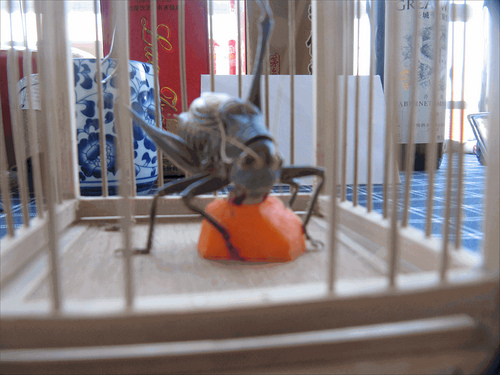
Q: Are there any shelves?
A: No, there are no shelves.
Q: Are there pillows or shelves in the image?
A: No, there are no shelves or pillows.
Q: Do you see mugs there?
A: Yes, there is a mug.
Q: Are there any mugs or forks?
A: Yes, there is a mug.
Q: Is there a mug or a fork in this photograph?
A: Yes, there is a mug.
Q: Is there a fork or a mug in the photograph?
A: Yes, there is a mug.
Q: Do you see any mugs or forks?
A: Yes, there is a mug.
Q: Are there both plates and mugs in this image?
A: No, there is a mug but no plates.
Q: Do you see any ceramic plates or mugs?
A: Yes, there is a porcelain mug.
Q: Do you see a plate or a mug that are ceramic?
A: Yes, the mug is ceramic.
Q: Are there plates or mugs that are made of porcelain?
A: Yes, the mug is made of porcelain.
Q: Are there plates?
A: No, there are no plates.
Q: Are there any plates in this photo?
A: No, there are no plates.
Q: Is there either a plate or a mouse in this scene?
A: No, there are no plates or computer mice.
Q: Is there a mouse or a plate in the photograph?
A: No, there are no plates or computer mice.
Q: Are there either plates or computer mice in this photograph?
A: No, there are no plates or computer mice.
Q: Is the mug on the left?
A: Yes, the mug is on the left of the image.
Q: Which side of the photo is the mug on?
A: The mug is on the left of the image.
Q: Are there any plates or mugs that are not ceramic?
A: No, there is a mug but it is ceramic.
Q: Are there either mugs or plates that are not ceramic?
A: No, there is a mug but it is ceramic.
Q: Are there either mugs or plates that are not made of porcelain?
A: No, there is a mug but it is made of porcelain.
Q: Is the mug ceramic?
A: Yes, the mug is ceramic.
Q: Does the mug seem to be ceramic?
A: Yes, the mug is ceramic.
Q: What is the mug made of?
A: The mug is made of porcelain.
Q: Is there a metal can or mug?
A: No, there is a mug but it is ceramic.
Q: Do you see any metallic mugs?
A: No, there is a mug but it is ceramic.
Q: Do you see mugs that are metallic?
A: No, there is a mug but it is ceramic.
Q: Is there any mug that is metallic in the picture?
A: No, there is a mug but it is ceramic.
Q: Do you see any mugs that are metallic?
A: No, there is a mug but it is ceramic.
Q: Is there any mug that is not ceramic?
A: No, there is a mug but it is ceramic.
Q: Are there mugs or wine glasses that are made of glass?
A: No, there is a mug but it is made of porcelain.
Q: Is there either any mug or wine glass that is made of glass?
A: No, there is a mug but it is made of porcelain.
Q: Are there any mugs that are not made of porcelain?
A: No, there is a mug but it is made of porcelain.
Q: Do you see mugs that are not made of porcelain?
A: No, there is a mug but it is made of porcelain.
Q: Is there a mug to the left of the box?
A: Yes, there is a mug to the left of the box.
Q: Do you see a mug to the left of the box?
A: Yes, there is a mug to the left of the box.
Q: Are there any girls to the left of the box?
A: No, there is a mug to the left of the box.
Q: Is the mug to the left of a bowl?
A: No, the mug is to the left of the box.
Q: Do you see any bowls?
A: No, there are no bowls.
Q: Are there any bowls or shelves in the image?
A: No, there are no bowls or shelves.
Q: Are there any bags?
A: No, there are no bags.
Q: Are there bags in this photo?
A: No, there are no bags.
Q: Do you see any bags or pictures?
A: No, there are no bags or pictures.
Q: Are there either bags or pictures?
A: No, there are no bags or pictures.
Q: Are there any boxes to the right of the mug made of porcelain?
A: Yes, there is a box to the right of the mug.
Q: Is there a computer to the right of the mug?
A: No, there is a box to the right of the mug.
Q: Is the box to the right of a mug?
A: Yes, the box is to the right of a mug.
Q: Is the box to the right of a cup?
A: No, the box is to the right of a mug.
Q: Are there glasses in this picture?
A: No, there are no glasses.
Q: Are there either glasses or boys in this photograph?
A: No, there are no glasses or boys.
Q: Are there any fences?
A: No, there are no fences.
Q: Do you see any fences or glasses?
A: No, there are no fences or glasses.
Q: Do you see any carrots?
A: Yes, there is a carrot.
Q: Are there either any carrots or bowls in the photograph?
A: Yes, there is a carrot.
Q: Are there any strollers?
A: No, there are no strollers.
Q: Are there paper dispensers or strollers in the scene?
A: No, there are no strollers or paper dispensers.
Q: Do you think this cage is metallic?
A: Yes, the cage is metallic.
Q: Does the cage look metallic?
A: Yes, the cage is metallic.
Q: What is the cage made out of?
A: The cage is made of metal.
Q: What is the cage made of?
A: The cage is made of metal.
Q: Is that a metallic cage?
A: Yes, that is a metallic cage.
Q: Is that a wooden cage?
A: No, that is a metallic cage.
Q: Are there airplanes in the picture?
A: No, there are no airplanes.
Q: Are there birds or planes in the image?
A: No, there are no planes or birds.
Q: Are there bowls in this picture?
A: No, there are no bowls.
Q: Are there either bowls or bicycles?
A: No, there are no bowls or bicycles.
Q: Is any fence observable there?
A: No, there are no fences.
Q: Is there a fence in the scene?
A: No, there are no fences.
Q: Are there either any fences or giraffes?
A: No, there are no fences or giraffes.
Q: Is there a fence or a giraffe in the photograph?
A: No, there are no fences or giraffes.